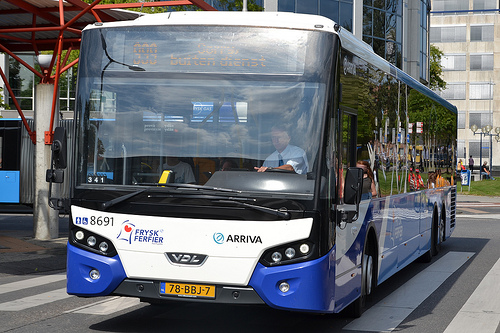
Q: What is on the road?
A: A bus.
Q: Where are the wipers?
A: On the windshield.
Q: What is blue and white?
A: The bus.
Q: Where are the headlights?
A: On the bus.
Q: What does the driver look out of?
A: The front windshield.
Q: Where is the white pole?
A: On the walkway.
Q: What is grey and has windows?
A: Building.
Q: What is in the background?
A: Building.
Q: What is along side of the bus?
A: Windows.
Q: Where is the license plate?
A: Front of bus.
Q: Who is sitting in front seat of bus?
A: Bus driver.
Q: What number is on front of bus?
A: 8691.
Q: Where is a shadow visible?
A: On ground.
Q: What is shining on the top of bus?
A: Sunlight.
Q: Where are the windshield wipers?
A: Front windows.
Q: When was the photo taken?
A: Outdoors.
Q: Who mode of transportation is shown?
A: Bus.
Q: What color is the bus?
A: Blue and white.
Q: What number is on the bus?
A: 8691.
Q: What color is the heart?
A: Red.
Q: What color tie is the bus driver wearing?
A: Blue.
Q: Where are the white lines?
A: Street.